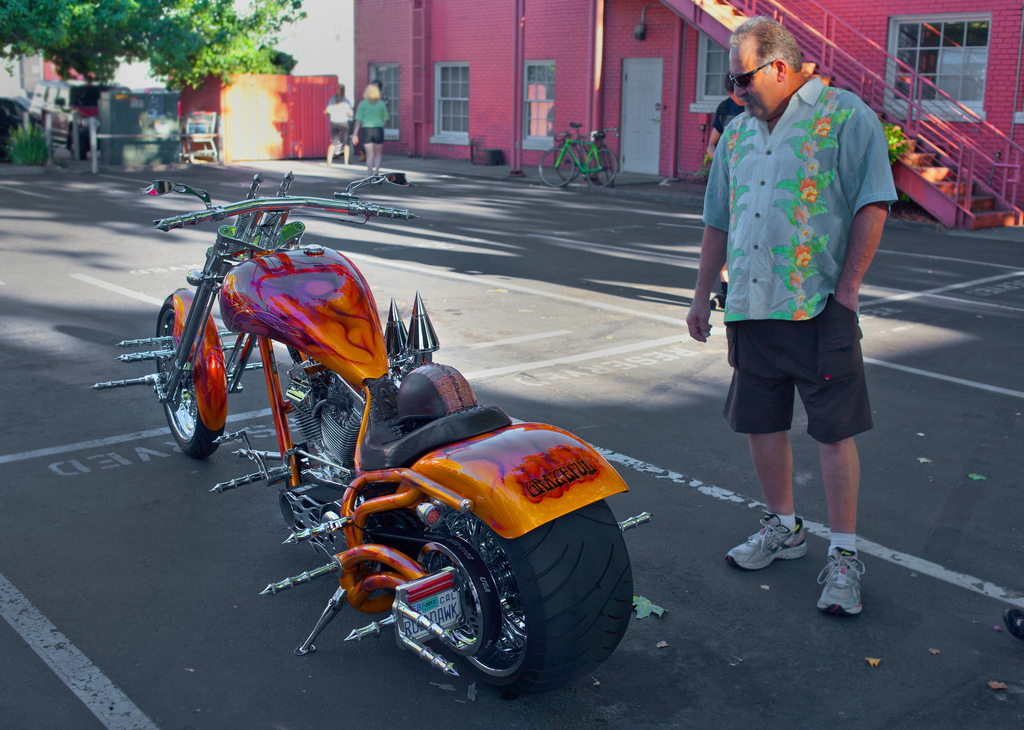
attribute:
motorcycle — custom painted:
[91, 166, 660, 705]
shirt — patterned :
[685, 80, 905, 322]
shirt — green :
[350, 96, 393, 131]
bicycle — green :
[536, 120, 622, 188]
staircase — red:
[660, 4, 1016, 221]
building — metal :
[350, 4, 1017, 205]